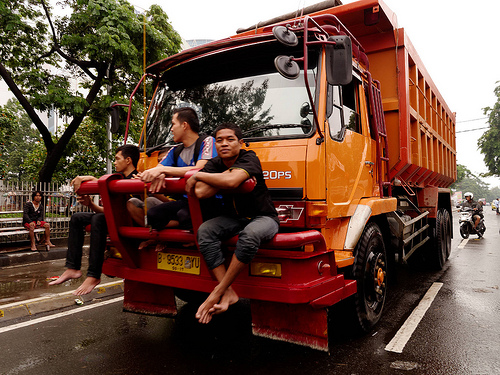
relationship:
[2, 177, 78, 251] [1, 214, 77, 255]
fence behind bench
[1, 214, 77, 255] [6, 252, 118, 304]
bench on sidewalk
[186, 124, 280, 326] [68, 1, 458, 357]
boys ride front of truck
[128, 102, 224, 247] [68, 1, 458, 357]
man ride front of truck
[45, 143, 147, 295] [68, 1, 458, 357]
man ride front of truck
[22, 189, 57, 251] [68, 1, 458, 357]
man watches truck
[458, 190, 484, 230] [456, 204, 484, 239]
man of motorbike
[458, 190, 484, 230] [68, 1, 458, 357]
man trails truck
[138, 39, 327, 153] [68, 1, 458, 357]
windshield of truck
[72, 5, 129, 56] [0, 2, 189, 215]
leaves of tree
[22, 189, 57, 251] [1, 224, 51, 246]
man sitting on bench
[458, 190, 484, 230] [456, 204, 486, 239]
man on motorbike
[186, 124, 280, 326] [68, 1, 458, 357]
boys on front of truck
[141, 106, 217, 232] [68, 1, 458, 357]
man on front of truck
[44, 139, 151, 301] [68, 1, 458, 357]
man on front of truck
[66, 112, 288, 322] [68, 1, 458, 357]
boys sitting truck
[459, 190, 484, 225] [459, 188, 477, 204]
man has helmet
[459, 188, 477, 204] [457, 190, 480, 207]
helmet on head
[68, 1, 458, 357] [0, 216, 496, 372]
truck on road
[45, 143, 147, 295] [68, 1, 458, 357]
man sitting in front of truck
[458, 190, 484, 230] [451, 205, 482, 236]
man on motorbike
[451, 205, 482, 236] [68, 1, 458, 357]
motorbike behind truck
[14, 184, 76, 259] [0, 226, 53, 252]
man sitting on bench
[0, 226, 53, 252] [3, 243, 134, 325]
bench on sidewalk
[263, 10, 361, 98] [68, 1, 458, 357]
mirrors on truck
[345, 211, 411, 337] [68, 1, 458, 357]
tire of truck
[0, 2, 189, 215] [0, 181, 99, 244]
tree growing behind fence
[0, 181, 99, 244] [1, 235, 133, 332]
fence on sidewalk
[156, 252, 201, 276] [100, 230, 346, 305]
license plate on bumper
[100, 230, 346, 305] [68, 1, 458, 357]
bumper on truck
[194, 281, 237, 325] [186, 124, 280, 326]
feet of boys